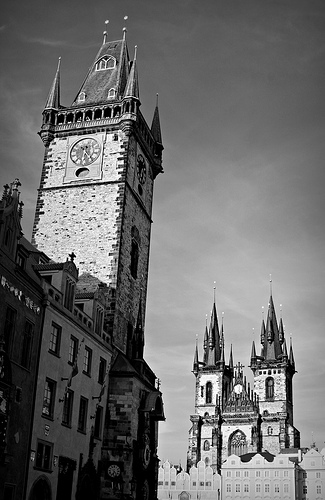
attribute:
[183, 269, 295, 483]
tower — tall 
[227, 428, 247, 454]
door — large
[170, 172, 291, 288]
sky — clear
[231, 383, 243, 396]
clock — on top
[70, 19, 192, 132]
building — tallest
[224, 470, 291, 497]
windows — small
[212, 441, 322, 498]
building — small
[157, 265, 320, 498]
cathedral — large 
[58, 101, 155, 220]
building — tall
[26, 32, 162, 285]
building — small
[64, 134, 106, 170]
clock —  tower's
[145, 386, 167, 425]
overhanging eve — small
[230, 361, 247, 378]
cross — on top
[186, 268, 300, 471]
building — tall, large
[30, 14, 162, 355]
tower —  tall 